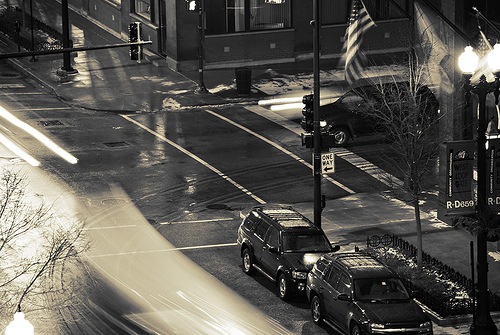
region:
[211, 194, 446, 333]
two black cars in a road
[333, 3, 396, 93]
an American flag in a pole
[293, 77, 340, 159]
a traffic light on a pole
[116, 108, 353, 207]
white lines on corner of street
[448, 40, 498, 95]
two street lights on top of a pole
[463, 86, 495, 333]
pole holding lights is black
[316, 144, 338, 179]
a sign on a pole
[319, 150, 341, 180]
white sign has black letters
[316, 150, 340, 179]
a black arrow pointing to the left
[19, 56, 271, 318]
road of street is wet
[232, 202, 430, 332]
two cars parked in the street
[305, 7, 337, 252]
large black pole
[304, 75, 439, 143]
car parked in a crossroad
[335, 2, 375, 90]
united states flag hanging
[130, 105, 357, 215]
white lines in the street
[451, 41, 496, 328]
large black lamppost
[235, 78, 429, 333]
three cars in a street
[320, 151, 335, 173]
white small signboard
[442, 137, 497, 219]
R-de59 signboard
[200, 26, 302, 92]
big black and gray board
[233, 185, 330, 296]
vehicle parked on street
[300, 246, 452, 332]
vehicle parked on street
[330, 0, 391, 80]
flag hanging on building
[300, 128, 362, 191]
traffic sign on pole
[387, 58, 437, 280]
tree on side walk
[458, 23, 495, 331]
light pole on side walk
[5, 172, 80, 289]
tree branches on sdie of steet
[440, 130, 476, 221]
sign on light pole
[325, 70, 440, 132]
vehicle driving on street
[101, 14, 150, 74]
traffic light on pole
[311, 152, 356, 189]
one way sign.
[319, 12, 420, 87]
American flag.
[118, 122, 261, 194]
a patch of street.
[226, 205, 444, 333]
Two black automobiles.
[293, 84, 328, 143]
street lights and signals.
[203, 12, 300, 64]
Part of a building.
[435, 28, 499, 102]
Lit street lamps.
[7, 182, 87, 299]
a patch of barren tree branches.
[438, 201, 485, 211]
a street sign and location.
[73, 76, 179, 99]
a wet patch of a sidewalk.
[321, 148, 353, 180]
a black and white sign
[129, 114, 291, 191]
white lines in the crosswalk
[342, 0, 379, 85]
an american flag waving in the wind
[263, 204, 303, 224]
a luggage rack on the roof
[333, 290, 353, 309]
a sideview mirror on an SUV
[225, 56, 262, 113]
a black trash can on the corner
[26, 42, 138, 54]
a pole supporting the traffic light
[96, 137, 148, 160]
a vent in the street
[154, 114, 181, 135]
light reflecting on the wet street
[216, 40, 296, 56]
white squares on the wall